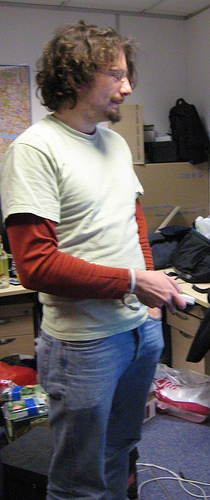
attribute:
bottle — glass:
[0, 242, 11, 289]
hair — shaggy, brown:
[34, 19, 141, 115]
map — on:
[0, 64, 32, 167]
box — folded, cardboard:
[124, 120, 144, 135]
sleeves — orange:
[12, 199, 159, 298]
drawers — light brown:
[0, 300, 37, 364]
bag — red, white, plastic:
[1, 340, 44, 398]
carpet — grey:
[136, 414, 209, 499]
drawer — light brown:
[163, 304, 209, 340]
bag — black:
[169, 216, 208, 285]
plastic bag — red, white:
[149, 362, 209, 425]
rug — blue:
[32, 414, 209, 494]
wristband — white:
[128, 265, 135, 293]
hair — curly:
[45, 51, 65, 90]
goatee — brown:
[102, 108, 121, 125]